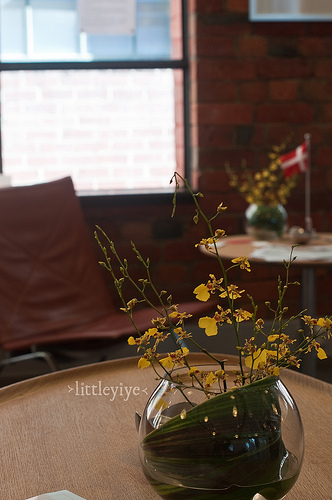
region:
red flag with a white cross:
[271, 122, 320, 246]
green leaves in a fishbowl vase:
[139, 377, 298, 482]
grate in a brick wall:
[221, 0, 330, 64]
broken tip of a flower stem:
[156, 157, 197, 237]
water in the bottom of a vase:
[132, 449, 321, 489]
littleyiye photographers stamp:
[59, 371, 155, 405]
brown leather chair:
[2, 178, 217, 368]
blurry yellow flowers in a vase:
[226, 120, 301, 259]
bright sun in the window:
[3, 26, 205, 189]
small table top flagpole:
[299, 128, 315, 246]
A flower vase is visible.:
[118, 367, 242, 487]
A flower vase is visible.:
[161, 321, 240, 474]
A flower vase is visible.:
[170, 388, 234, 476]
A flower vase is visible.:
[205, 403, 271, 486]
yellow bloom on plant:
[229, 253, 251, 272]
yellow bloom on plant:
[197, 308, 231, 340]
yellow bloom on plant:
[301, 340, 327, 361]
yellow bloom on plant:
[137, 355, 151, 371]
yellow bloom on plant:
[213, 203, 224, 219]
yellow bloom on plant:
[161, 356, 179, 369]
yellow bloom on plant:
[199, 372, 221, 386]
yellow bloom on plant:
[191, 368, 200, 379]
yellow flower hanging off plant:
[195, 311, 222, 344]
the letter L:
[64, 374, 83, 409]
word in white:
[41, 365, 151, 422]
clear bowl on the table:
[126, 359, 311, 475]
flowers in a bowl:
[115, 266, 298, 413]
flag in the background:
[275, 153, 310, 191]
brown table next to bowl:
[5, 400, 107, 467]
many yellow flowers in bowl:
[128, 246, 288, 390]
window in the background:
[30, 10, 115, 123]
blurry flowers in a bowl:
[231, 149, 288, 241]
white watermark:
[64, 375, 147, 403]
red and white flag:
[275, 143, 310, 182]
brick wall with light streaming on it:
[1, 72, 174, 187]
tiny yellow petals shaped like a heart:
[196, 311, 220, 336]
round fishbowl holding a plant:
[96, 171, 331, 499]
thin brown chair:
[0, 175, 219, 355]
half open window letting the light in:
[0, 2, 195, 195]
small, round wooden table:
[198, 217, 331, 318]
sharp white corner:
[61, 485, 69, 494]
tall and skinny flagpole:
[302, 134, 315, 235]